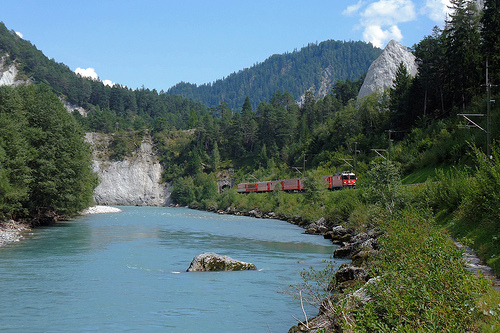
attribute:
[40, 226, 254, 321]
water — calm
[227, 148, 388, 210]
train — red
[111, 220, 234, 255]
waves — small 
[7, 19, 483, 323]
range — tree filled mountain 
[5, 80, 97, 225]
trees — green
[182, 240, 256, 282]
rock — large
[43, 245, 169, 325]
water — middle 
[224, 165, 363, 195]
train — red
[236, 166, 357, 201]
train — large red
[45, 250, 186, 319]
water — side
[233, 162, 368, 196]
train — red 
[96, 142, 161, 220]
wall — large white rock 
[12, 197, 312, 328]
water — edge 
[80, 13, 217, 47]
sky — blue 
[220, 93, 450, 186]
forest — Section 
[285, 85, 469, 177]
forest — Section 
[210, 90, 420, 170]
forest — Section 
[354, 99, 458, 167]
forest — Section 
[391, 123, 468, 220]
forest — Section 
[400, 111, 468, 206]
forest — Section 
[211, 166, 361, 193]
train — red, gray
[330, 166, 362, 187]
train front — black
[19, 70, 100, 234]
evergreen tree — green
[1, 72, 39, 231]
evergreen tree — green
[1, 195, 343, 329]
river — clear, blue, large, wide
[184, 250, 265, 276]
rock — large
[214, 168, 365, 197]
train — large, long, red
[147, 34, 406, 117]
mountain — large, green, forested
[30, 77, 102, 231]
tree — large, round, green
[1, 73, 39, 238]
tree — large, round, green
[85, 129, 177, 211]
cliff face — grey, white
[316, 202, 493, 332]
bushes — large, long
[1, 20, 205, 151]
hill — large, green, tree covered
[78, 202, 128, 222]
hill ground — white, round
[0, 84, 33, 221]
tree — large, tall, leafy, green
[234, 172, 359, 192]
train — large, long, red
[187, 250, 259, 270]
rock — large, jagged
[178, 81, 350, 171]
hill — large, green, forested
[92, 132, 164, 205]
cliff — large, wide, grey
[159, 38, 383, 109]
mountain — large, tall, green, forested